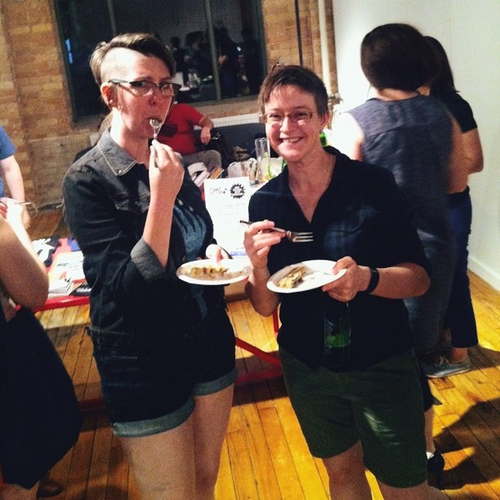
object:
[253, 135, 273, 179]
glass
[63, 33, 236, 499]
woman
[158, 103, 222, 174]
man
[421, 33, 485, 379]
woman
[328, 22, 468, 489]
woman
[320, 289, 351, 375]
beer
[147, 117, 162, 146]
fork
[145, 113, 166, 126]
lady's mouth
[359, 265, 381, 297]
wristwatch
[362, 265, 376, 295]
lady's wrist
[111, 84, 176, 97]
glasses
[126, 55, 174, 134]
lady's face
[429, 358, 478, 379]
shoes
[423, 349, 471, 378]
lady's foot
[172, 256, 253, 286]
plate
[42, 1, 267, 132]
window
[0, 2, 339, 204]
wall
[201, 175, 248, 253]
paper sign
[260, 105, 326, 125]
glasses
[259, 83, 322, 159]
woman's face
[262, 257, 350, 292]
plate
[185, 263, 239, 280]
food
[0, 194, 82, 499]
person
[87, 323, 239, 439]
shorts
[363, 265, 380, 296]
wristband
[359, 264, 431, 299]
arm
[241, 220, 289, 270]
hand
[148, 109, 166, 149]
utensil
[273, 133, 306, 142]
smiling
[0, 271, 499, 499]
floor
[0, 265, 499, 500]
brown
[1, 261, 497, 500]
wooden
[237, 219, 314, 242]
fork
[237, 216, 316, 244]
metal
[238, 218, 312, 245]
silver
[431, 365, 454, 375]
blue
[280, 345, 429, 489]
shorts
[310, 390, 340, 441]
green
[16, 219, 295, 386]
table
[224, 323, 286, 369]
leg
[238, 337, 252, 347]
red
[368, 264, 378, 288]
black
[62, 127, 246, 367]
shirt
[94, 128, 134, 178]
collar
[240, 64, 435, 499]
woman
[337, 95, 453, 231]
shirt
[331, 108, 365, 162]
sleeveless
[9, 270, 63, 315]
elbow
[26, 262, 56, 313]
bent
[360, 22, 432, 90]
hair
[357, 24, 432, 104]
short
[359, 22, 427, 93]
brown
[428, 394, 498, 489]
shadow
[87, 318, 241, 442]
shorts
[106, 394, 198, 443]
cuff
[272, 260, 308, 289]
food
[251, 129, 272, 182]
tall